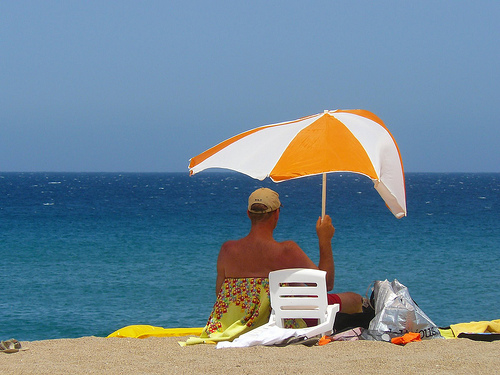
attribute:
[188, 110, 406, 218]
umbrella — white, orange, yellow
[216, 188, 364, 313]
man — without shirt, tanned, by himself, trying to not tan, caucasian, sitting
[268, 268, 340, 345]
beach chair — white, small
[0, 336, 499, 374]
sand — tan, brown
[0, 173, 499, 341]
water — ocean, blue, calm, blue green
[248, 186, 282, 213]
hat — yellow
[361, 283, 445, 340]
bag — silver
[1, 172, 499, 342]
ocean — blue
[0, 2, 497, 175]
sky — clear, with no clouds, blue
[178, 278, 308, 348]
beach towel — green, flowered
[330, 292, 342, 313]
shorts — red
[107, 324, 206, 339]
beach toy — yellow, inflatable